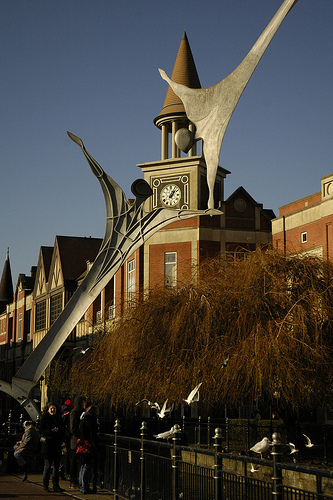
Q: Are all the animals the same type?
A: Yes, all the animals are birds.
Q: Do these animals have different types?
A: No, all the animals are birds.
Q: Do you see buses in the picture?
A: No, there are no buses.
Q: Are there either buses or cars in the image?
A: No, there are no buses or cars.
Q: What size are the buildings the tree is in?
A: The buildings are large.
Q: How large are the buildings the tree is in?
A: The buildings are large.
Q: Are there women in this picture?
A: Yes, there is a woman.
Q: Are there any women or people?
A: Yes, there is a woman.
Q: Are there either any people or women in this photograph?
A: Yes, there is a woman.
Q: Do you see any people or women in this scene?
A: Yes, there is a woman.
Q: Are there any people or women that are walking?
A: Yes, the woman is walking.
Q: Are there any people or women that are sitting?
A: Yes, the woman is sitting.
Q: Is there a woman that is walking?
A: Yes, there is a woman that is walking.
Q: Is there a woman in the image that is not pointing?
A: Yes, there is a woman that is walking.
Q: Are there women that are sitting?
A: Yes, there is a woman that is sitting.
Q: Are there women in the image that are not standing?
A: Yes, there is a woman that is sitting.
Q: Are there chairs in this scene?
A: No, there are no chairs.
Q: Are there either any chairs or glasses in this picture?
A: No, there are no chairs or glasses.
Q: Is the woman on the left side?
A: Yes, the woman is on the left of the image.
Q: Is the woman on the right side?
A: No, the woman is on the left of the image.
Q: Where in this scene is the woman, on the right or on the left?
A: The woman is on the left of the image.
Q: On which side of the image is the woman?
A: The woman is on the left of the image.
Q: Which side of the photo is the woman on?
A: The woman is on the left of the image.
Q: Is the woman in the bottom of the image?
A: Yes, the woman is in the bottom of the image.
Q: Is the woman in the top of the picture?
A: No, the woman is in the bottom of the image.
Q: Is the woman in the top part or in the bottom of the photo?
A: The woman is in the bottom of the image.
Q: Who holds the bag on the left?
A: The woman holds the bag.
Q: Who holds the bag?
A: The woman holds the bag.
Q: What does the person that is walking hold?
A: The woman holds the bag.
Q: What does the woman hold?
A: The woman holds the bag.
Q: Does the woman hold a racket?
A: No, the woman holds the bag.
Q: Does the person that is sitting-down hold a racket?
A: No, the woman holds the bag.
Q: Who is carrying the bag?
A: The woman is carrying the bag.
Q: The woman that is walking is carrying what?
A: The woman is carrying a bag.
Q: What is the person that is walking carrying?
A: The woman is carrying a bag.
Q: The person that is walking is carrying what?
A: The woman is carrying a bag.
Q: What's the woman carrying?
A: The woman is carrying a bag.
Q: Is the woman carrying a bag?
A: Yes, the woman is carrying a bag.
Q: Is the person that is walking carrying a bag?
A: Yes, the woman is carrying a bag.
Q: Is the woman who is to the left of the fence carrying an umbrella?
A: No, the woman is carrying a bag.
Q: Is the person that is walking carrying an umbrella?
A: No, the woman is carrying a bag.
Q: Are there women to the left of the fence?
A: Yes, there is a woman to the left of the fence.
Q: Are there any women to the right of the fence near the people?
A: No, the woman is to the left of the fence.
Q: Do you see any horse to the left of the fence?
A: No, there is a woman to the left of the fence.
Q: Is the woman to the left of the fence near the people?
A: Yes, the woman is to the left of the fence.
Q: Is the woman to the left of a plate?
A: No, the woman is to the left of the fence.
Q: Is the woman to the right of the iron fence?
A: No, the woman is to the left of the fence.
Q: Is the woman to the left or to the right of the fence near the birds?
A: The woman is to the left of the fence.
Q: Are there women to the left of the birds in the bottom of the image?
A: Yes, there is a woman to the left of the birds.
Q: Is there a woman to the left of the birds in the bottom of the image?
A: Yes, there is a woman to the left of the birds.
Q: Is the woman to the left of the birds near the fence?
A: Yes, the woman is to the left of the birds.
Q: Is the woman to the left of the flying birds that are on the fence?
A: Yes, the woman is to the left of the birds.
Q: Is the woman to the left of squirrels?
A: No, the woman is to the left of the birds.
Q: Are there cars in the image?
A: No, there are no cars.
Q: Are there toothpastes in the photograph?
A: No, there are no toothpastes.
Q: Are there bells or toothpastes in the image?
A: No, there are no toothpastes or bells.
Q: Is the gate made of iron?
A: Yes, the gate is made of iron.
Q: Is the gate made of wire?
A: No, the gate is made of iron.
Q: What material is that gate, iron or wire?
A: The gate is made of iron.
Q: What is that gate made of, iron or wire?
A: The gate is made of iron.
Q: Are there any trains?
A: No, there are no trains.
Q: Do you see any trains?
A: No, there are no trains.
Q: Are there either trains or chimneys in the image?
A: No, there are no trains or chimneys.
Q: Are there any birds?
A: Yes, there are birds.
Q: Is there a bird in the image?
A: Yes, there are birds.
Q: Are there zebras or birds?
A: Yes, there are birds.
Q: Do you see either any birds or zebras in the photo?
A: Yes, there are birds.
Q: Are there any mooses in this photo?
A: No, there are no mooses.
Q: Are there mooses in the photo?
A: No, there are no mooses.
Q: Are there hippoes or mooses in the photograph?
A: No, there are no mooses or hippoes.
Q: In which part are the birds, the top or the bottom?
A: The birds are in the bottom of the image.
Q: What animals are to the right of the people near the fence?
A: The animals are birds.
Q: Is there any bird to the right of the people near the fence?
A: Yes, there are birds to the right of the people.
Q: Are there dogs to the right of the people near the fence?
A: No, there are birds to the right of the people.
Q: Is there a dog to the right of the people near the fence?
A: No, there are birds to the right of the people.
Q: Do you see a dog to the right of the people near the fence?
A: No, there are birds to the right of the people.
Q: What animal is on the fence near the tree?
A: The birds are on the fence.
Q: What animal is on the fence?
A: The birds are on the fence.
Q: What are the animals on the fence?
A: The animals are birds.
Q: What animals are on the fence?
A: The animals are birds.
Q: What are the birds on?
A: The birds are on the fence.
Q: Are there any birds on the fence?
A: Yes, there are birds on the fence.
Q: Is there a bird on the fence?
A: Yes, there are birds on the fence.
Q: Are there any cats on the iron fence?
A: No, there are birds on the fence.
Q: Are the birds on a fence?
A: Yes, the birds are on a fence.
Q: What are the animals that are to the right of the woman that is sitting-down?
A: The animals are birds.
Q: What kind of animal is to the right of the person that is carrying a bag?
A: The animals are birds.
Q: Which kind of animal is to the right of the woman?
A: The animals are birds.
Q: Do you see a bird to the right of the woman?
A: Yes, there are birds to the right of the woman.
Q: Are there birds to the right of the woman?
A: Yes, there are birds to the right of the woman.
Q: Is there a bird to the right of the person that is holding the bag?
A: Yes, there are birds to the right of the woman.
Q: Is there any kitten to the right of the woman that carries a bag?
A: No, there are birds to the right of the woman.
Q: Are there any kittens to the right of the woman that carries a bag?
A: No, there are birds to the right of the woman.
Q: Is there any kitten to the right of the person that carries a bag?
A: No, there are birds to the right of the woman.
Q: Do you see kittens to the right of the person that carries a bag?
A: No, there are birds to the right of the woman.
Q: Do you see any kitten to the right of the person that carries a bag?
A: No, there are birds to the right of the woman.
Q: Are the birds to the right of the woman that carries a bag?
A: Yes, the birds are to the right of the woman.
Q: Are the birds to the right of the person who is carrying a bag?
A: Yes, the birds are to the right of the woman.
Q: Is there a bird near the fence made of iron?
A: Yes, there are birds near the fence.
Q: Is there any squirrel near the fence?
A: No, there are birds near the fence.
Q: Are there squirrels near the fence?
A: No, there are birds near the fence.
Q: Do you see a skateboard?
A: No, there are no skateboards.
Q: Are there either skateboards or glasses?
A: No, there are no skateboards or glasses.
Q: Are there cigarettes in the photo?
A: No, there are no cigarettes.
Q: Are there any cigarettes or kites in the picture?
A: No, there are no cigarettes or kites.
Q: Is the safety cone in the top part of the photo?
A: Yes, the safety cone is in the top of the image.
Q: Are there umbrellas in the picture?
A: No, there are no umbrellas.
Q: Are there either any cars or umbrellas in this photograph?
A: No, there are no umbrellas or cars.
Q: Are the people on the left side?
A: Yes, the people are on the left of the image.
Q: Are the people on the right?
A: No, the people are on the left of the image.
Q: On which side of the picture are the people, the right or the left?
A: The people are on the left of the image.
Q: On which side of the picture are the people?
A: The people are on the left of the image.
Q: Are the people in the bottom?
A: Yes, the people are in the bottom of the image.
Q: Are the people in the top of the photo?
A: No, the people are in the bottom of the image.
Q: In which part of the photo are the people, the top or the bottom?
A: The people are in the bottom of the image.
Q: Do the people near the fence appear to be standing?
A: Yes, the people are standing.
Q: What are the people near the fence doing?
A: The people are standing.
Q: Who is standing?
A: The people are standing.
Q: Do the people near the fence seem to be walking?
A: No, the people are standing.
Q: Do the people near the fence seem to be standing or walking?
A: The people are standing.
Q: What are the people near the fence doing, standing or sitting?
A: The people are standing.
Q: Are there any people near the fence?
A: Yes, there are people near the fence.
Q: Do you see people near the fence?
A: Yes, there are people near the fence.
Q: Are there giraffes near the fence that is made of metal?
A: No, there are people near the fence.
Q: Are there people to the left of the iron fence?
A: Yes, there are people to the left of the fence.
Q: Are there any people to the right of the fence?
A: No, the people are to the left of the fence.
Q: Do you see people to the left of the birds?
A: Yes, there are people to the left of the birds.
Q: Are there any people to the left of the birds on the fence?
A: Yes, there are people to the left of the birds.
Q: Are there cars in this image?
A: No, there are no cars.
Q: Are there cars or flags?
A: No, there are no cars or flags.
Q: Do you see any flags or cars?
A: No, there are no cars or flags.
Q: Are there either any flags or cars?
A: No, there are no cars or flags.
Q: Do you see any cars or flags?
A: No, there are no cars or flags.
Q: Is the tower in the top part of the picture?
A: Yes, the tower is in the top of the image.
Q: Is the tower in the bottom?
A: No, the tower is in the top of the image.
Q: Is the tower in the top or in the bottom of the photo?
A: The tower is in the top of the image.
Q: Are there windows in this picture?
A: Yes, there are windows.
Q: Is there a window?
A: Yes, there are windows.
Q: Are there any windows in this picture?
A: Yes, there are windows.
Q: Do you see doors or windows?
A: Yes, there are windows.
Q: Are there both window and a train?
A: No, there are windows but no trains.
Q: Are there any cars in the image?
A: No, there are no cars.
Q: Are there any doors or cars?
A: No, there are no cars or doors.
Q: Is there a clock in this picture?
A: Yes, there is a clock.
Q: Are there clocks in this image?
A: Yes, there is a clock.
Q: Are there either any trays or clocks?
A: Yes, there is a clock.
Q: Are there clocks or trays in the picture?
A: Yes, there is a clock.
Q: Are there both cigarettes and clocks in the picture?
A: No, there is a clock but no cigarettes.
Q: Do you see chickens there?
A: No, there are no chickens.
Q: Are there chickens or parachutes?
A: No, there are no chickens or parachutes.